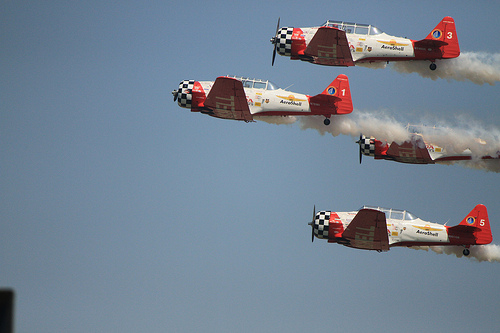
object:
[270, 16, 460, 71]
airplane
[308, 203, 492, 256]
airplane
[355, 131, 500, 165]
airplane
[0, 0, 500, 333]
clouds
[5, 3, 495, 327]
sky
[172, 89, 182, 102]
propeller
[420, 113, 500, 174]
smoke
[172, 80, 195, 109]
checkered front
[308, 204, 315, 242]
propeller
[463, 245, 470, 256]
landing gear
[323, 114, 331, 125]
landing gear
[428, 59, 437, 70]
landing gear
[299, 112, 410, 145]
smoke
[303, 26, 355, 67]
wing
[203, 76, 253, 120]
wing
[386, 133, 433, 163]
wing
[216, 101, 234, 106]
writing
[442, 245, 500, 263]
smoke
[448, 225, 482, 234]
stabilizer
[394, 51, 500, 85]
smoke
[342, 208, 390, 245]
wing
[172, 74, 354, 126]
airplane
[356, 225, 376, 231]
number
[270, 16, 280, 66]
propeller